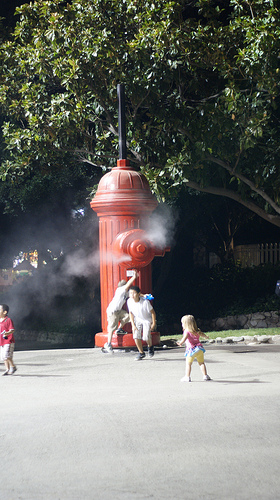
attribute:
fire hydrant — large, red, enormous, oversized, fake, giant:
[85, 79, 172, 354]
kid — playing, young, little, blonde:
[174, 309, 213, 385]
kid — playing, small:
[1, 297, 20, 384]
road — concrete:
[5, 342, 275, 488]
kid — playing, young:
[98, 278, 130, 353]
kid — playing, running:
[126, 282, 155, 362]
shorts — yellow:
[184, 349, 207, 368]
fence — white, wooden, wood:
[201, 237, 276, 270]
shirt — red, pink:
[2, 315, 15, 348]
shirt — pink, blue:
[183, 328, 200, 349]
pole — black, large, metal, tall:
[110, 80, 131, 165]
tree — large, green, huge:
[14, 8, 274, 222]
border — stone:
[205, 307, 275, 329]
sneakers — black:
[133, 344, 156, 362]